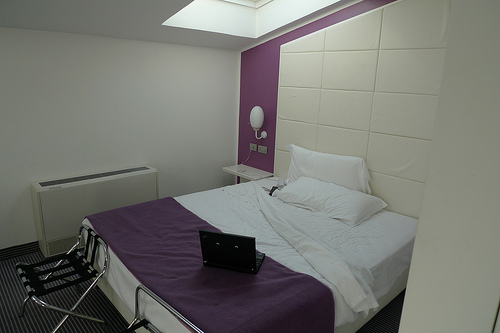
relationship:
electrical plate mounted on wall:
[257, 143, 270, 157] [240, 0, 400, 173]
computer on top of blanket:
[196, 226, 267, 274] [87, 198, 335, 333]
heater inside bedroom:
[30, 162, 159, 259] [1, 0, 499, 331]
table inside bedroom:
[220, 159, 274, 191] [1, 0, 499, 331]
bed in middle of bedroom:
[78, 175, 419, 332] [1, 0, 499, 331]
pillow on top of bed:
[273, 174, 390, 227] [78, 175, 419, 332]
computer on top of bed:
[196, 226, 267, 274] [78, 175, 419, 332]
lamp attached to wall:
[245, 102, 270, 141] [240, 0, 400, 173]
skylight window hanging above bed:
[160, 0, 340, 39] [78, 175, 419, 332]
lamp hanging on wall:
[245, 102, 270, 141] [240, 0, 400, 173]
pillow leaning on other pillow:
[273, 174, 390, 227] [283, 139, 373, 199]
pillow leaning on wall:
[283, 139, 373, 199] [272, 0, 450, 219]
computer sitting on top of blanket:
[196, 226, 267, 274] [87, 198, 335, 333]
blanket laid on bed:
[87, 198, 335, 333] [78, 175, 419, 332]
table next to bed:
[220, 159, 274, 191] [78, 175, 419, 332]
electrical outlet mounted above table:
[248, 141, 259, 153] [220, 159, 274, 191]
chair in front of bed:
[14, 223, 108, 330] [78, 175, 419, 332]